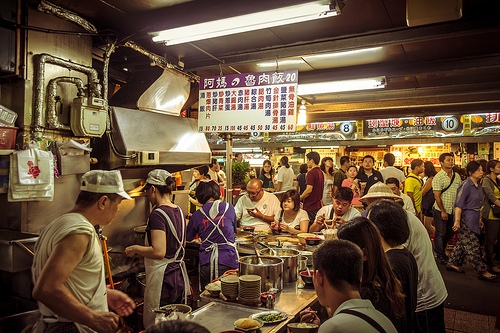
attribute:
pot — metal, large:
[235, 254, 286, 305]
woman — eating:
[269, 187, 310, 237]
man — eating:
[239, 176, 280, 228]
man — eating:
[310, 183, 362, 230]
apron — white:
[138, 204, 190, 317]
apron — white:
[68, 215, 117, 333]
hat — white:
[76, 165, 136, 202]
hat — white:
[134, 166, 175, 188]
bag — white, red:
[16, 144, 54, 186]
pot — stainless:
[259, 243, 301, 285]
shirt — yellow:
[402, 171, 427, 214]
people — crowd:
[215, 140, 485, 242]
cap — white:
[202, 281, 222, 297]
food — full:
[233, 245, 302, 299]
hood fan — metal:
[102, 105, 217, 177]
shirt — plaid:
[432, 169, 462, 218]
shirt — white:
[276, 165, 296, 189]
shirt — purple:
[455, 176, 490, 233]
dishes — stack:
[236, 273, 264, 305]